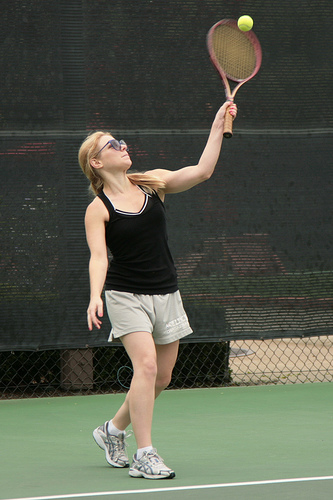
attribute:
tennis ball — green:
[228, 8, 273, 45]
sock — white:
[136, 449, 150, 454]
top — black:
[97, 182, 180, 294]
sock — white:
[134, 446, 154, 459]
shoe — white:
[120, 447, 175, 481]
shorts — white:
[104, 288, 193, 345]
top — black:
[87, 183, 180, 291]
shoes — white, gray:
[82, 416, 180, 490]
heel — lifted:
[89, 422, 119, 437]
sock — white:
[107, 419, 121, 437]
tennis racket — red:
[186, 11, 277, 151]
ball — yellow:
[234, 14, 253, 30]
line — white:
[176, 469, 329, 495]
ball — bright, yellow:
[236, 12, 253, 30]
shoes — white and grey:
[85, 422, 182, 482]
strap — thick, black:
[98, 194, 112, 208]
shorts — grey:
[92, 279, 204, 356]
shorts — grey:
[106, 292, 186, 340]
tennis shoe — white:
[129, 442, 175, 485]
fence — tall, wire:
[2, 0, 332, 402]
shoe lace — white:
[143, 446, 164, 462]